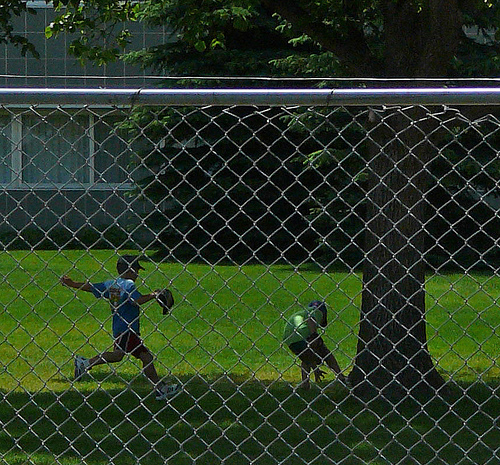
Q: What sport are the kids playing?
A: Baseball.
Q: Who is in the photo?
A: Two boys.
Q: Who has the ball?
A: Boy in green shirt.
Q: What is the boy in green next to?
A: Tree.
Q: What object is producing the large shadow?
A: Tree.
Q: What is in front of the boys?
A: Fence.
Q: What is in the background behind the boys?
A: Building.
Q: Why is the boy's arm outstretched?
A: He is catching or throwing.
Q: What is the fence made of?
A: Metal.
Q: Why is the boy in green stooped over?
A: He is trying to reach something.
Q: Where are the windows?
A: On the house.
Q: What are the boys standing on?
A: Green grass.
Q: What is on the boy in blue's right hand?
A: Glove.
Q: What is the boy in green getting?
A: Baseball.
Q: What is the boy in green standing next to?
A: Tree.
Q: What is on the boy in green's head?
A: Cap.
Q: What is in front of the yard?
A: Fence.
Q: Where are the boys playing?
A: In a yard.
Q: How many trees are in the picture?
A: One.